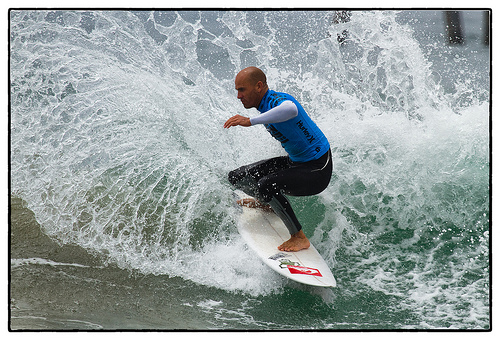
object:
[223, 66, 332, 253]
man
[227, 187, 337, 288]
surfboard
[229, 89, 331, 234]
wetsuit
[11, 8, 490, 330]
ocean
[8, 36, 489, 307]
wave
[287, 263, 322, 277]
logo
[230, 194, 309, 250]
foot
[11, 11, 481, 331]
water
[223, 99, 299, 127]
arm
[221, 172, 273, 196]
knee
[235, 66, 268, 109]
head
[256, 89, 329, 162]
shirt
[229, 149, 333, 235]
pants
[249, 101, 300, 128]
sleeve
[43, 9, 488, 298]
surf spray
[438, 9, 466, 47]
pillar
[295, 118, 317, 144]
logo